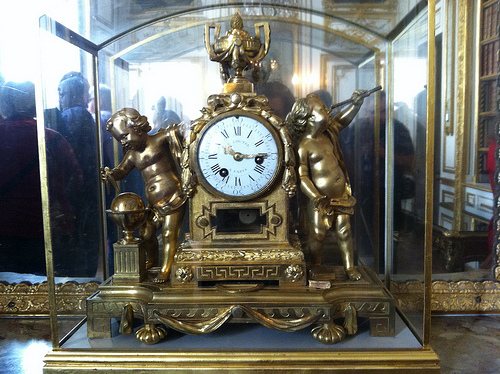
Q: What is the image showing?
A: It is showing a museum.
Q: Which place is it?
A: It is a museum.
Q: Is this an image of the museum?
A: Yes, it is showing the museum.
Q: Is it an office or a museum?
A: It is a museum.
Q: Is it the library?
A: No, it is the museum.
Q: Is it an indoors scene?
A: Yes, it is indoors.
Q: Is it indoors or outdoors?
A: It is indoors.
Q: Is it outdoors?
A: No, it is indoors.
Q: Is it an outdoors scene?
A: No, it is indoors.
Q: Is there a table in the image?
A: Yes, there is a table.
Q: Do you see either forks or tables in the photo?
A: Yes, there is a table.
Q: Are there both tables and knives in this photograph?
A: No, there is a table but no knives.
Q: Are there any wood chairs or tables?
A: Yes, there is a wood table.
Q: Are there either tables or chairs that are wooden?
A: Yes, the table is wooden.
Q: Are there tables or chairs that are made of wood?
A: Yes, the table is made of wood.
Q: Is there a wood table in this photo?
A: Yes, there is a wood table.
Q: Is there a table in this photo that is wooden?
A: Yes, there is a table that is wooden.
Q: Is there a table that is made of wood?
A: Yes, there is a table that is made of wood.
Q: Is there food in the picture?
A: No, there is no food.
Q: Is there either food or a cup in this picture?
A: No, there are no food or cups.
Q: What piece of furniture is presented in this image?
A: The piece of furniture is a table.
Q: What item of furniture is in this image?
A: The piece of furniture is a table.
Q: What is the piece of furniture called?
A: The piece of furniture is a table.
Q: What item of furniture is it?
A: The piece of furniture is a table.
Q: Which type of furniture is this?
A: This is a table.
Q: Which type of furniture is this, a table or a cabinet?
A: This is a table.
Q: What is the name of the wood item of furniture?
A: The piece of furniture is a table.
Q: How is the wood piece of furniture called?
A: The piece of furniture is a table.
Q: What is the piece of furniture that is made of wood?
A: The piece of furniture is a table.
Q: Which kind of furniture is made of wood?
A: The furniture is a table.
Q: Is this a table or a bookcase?
A: This is a table.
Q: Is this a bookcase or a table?
A: This is a table.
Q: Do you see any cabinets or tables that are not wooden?
A: No, there is a table but it is wooden.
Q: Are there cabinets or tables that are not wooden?
A: No, there is a table but it is wooden.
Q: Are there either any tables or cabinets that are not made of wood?
A: No, there is a table but it is made of wood.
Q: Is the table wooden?
A: Yes, the table is wooden.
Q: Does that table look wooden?
A: Yes, the table is wooden.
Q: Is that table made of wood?
A: Yes, the table is made of wood.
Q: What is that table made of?
A: The table is made of wood.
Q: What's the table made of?
A: The table is made of wood.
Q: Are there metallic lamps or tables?
A: No, there is a table but it is wooden.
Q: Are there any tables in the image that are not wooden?
A: No, there is a table but it is wooden.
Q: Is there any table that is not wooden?
A: No, there is a table but it is wooden.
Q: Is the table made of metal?
A: No, the table is made of wood.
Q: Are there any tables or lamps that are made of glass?
A: No, there is a table but it is made of wood.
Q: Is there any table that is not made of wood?
A: No, there is a table but it is made of wood.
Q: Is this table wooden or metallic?
A: The table is wooden.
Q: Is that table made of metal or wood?
A: The table is made of wood.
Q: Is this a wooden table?
A: Yes, this is a wooden table.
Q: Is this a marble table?
A: No, this is a wooden table.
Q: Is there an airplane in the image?
A: No, there are no airplanes.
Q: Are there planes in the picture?
A: No, there are no planes.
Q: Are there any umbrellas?
A: No, there are no umbrellas.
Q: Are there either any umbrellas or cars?
A: No, there are no umbrellas or cars.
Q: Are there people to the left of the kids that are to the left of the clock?
A: Yes, there are people to the left of the kids.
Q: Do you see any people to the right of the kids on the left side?
A: No, the people are to the left of the kids.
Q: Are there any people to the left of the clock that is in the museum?
A: Yes, there are people to the left of the clock.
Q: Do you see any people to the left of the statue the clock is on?
A: Yes, there are people to the left of the statue.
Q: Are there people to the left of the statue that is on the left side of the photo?
A: Yes, there are people to the left of the statue.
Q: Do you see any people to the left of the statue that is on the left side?
A: Yes, there are people to the left of the statue.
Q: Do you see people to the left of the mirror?
A: Yes, there are people to the left of the mirror.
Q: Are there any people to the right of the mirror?
A: No, the people are to the left of the mirror.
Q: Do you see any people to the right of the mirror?
A: No, the people are to the left of the mirror.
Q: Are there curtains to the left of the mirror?
A: No, there are people to the left of the mirror.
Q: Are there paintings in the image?
A: No, there are no paintings.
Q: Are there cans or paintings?
A: No, there are no paintings or cans.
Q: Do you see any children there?
A: Yes, there are children.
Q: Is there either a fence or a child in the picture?
A: Yes, there are children.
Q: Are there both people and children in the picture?
A: Yes, there are both children and a person.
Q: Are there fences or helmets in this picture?
A: No, there are no fences or helmets.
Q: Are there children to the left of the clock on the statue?
A: Yes, there are children to the left of the clock.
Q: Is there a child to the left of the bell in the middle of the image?
A: Yes, there are children to the left of the bell.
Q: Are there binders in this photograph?
A: No, there are no binders.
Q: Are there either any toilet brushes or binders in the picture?
A: No, there are no binders or toilet brushes.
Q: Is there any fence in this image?
A: No, there are no fences.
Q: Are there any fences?
A: No, there are no fences.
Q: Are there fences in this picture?
A: No, there are no fences.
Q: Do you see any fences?
A: No, there are no fences.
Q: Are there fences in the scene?
A: No, there are no fences.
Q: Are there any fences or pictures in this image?
A: No, there are no fences or pictures.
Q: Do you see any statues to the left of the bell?
A: Yes, there is a statue to the left of the bell.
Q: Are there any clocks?
A: Yes, there is a clock.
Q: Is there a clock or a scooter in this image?
A: Yes, there is a clock.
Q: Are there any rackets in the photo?
A: No, there are no rackets.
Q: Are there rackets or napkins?
A: No, there are no rackets or napkins.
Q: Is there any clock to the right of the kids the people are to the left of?
A: Yes, there is a clock to the right of the kids.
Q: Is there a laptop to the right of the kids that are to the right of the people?
A: No, there is a clock to the right of the kids.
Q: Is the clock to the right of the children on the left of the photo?
A: Yes, the clock is to the right of the children.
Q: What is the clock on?
A: The clock is on the statue.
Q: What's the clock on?
A: The clock is on the statue.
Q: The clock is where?
A: The clock is in the museum.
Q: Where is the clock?
A: The clock is in the museum.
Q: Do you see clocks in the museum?
A: Yes, there is a clock in the museum.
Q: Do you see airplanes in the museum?
A: No, there is a clock in the museum.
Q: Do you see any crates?
A: No, there are no crates.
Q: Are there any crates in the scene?
A: No, there are no crates.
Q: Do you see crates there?
A: No, there are no crates.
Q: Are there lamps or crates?
A: No, there are no crates or lamps.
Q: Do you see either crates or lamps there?
A: No, there are no crates or lamps.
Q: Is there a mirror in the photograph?
A: Yes, there is a mirror.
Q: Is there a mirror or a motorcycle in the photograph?
A: Yes, there is a mirror.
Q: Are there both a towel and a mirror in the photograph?
A: No, there is a mirror but no towels.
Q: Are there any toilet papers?
A: No, there are no toilet papers.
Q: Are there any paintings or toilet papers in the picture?
A: No, there are no toilet papers or paintings.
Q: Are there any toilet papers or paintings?
A: No, there are no toilet papers or paintings.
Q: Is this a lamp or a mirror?
A: This is a mirror.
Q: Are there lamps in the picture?
A: No, there are no lamps.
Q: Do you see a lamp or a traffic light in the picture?
A: No, there are no lamps or traffic lights.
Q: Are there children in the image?
A: Yes, there are children.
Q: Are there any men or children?
A: Yes, there are children.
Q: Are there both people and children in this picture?
A: Yes, there are both children and people.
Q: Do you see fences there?
A: No, there are no fences.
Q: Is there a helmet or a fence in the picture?
A: No, there are no fences or helmets.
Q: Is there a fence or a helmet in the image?
A: No, there are no fences or helmets.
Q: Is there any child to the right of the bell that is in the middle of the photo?
A: Yes, there are children to the right of the bell.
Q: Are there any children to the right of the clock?
A: Yes, there are children to the right of the clock.